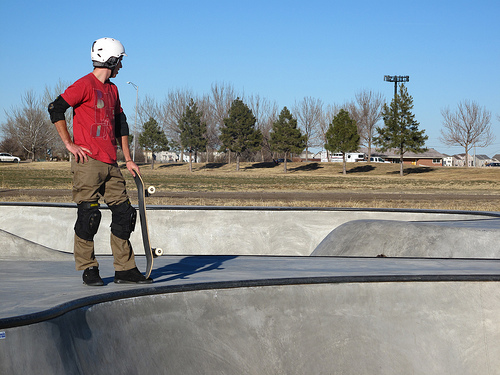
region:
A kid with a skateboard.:
[46, 37, 163, 288]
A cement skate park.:
[3, 200, 496, 372]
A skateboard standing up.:
[131, 170, 163, 281]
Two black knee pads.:
[73, 200, 138, 241]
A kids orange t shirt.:
[58, 71, 125, 166]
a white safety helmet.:
[88, 35, 127, 79]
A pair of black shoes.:
[81, 266, 156, 287]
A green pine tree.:
[323, 110, 362, 176]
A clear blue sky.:
[1, 2, 498, 156]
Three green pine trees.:
[213, 95, 361, 177]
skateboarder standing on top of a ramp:
[34, 19, 167, 288]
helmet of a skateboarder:
[82, 33, 134, 73]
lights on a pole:
[379, 69, 422, 91]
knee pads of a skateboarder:
[67, 197, 143, 243]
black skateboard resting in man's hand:
[129, 166, 169, 289]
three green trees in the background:
[172, 92, 314, 167]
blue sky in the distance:
[12, 3, 476, 35]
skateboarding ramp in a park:
[8, 277, 494, 354]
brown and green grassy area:
[173, 171, 498, 196]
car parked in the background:
[1, 147, 23, 170]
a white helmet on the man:
[86, 30, 128, 70]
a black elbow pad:
[39, 91, 76, 124]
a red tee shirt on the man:
[57, 68, 132, 168]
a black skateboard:
[129, 161, 164, 281]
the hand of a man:
[63, 134, 94, 165]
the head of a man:
[89, 30, 128, 80]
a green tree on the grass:
[216, 88, 264, 168]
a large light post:
[381, 68, 412, 110]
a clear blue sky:
[0, 0, 499, 158]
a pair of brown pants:
[70, 142, 151, 272]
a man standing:
[57, 23, 197, 275]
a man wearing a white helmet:
[41, 4, 210, 269]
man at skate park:
[43, 10, 240, 305]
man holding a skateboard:
[41, 16, 245, 298]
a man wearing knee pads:
[22, 6, 197, 304]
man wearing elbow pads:
[52, 15, 179, 287]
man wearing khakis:
[32, 20, 227, 295]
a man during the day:
[24, 24, 256, 353]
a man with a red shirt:
[22, 40, 205, 277]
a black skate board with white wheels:
[113, 151, 204, 296]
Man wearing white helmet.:
[77, 28, 140, 81]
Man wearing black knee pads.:
[65, 197, 160, 238]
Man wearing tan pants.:
[54, 162, 166, 284]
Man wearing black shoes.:
[73, 253, 165, 294]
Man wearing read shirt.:
[68, 74, 120, 149]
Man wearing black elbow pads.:
[45, 80, 84, 145]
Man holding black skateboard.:
[114, 123, 169, 276]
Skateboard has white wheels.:
[138, 160, 161, 331]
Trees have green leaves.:
[134, 100, 393, 150]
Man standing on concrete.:
[44, 222, 223, 372]